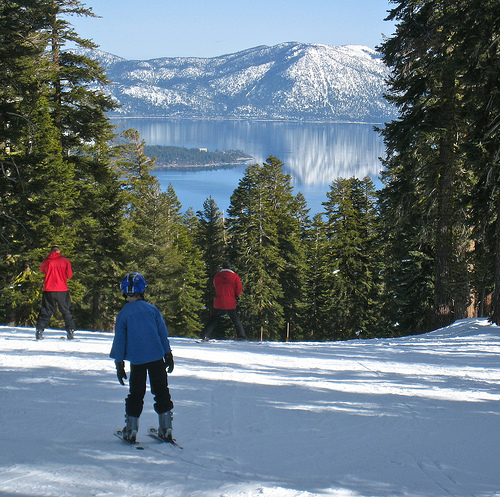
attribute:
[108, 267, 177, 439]
child — skiing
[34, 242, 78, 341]
person — skiing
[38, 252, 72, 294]
jacket — red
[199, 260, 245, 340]
person — skiing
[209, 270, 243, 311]
jacket — red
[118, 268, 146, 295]
helmet — blue, black, striped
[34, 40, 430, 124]
mountain — snow covered, large, snow capped, distant, snowy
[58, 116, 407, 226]
lake — remote, reflective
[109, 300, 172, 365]
jacket — blue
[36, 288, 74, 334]
pants — black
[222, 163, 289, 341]
tree — green, dark green, tall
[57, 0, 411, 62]
sky — pale blue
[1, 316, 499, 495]
ground — snowy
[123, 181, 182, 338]
tree — dark green, tall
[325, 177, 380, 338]
tree — dark green, tall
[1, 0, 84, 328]
tree — dark green, tall, large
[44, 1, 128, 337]
tree — large, dark green, tall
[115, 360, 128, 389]
glove — black